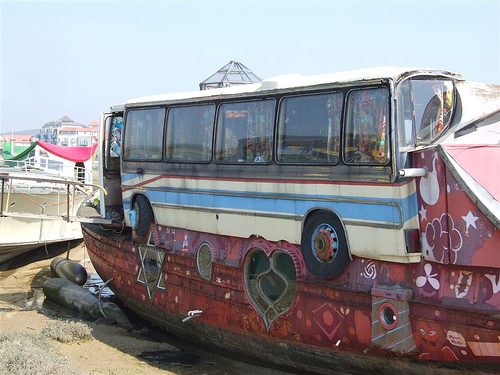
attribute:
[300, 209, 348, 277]
wheel — black, large, rear wheel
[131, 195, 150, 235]
wheel — black, left tire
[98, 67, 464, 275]
bus — blue, white, large, still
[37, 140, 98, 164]
roof — pink, red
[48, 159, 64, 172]
window — small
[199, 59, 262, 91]
dome — glass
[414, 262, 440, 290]
clover — white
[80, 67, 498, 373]
boat — red, custom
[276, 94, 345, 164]
window — empty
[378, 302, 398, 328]
hole — round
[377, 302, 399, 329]
edge — red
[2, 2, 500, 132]
sky — clear, blue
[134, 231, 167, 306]
star of david — window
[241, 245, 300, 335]
heart — window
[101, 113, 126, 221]
door — open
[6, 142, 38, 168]
roof — green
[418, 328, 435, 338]
eyes — white